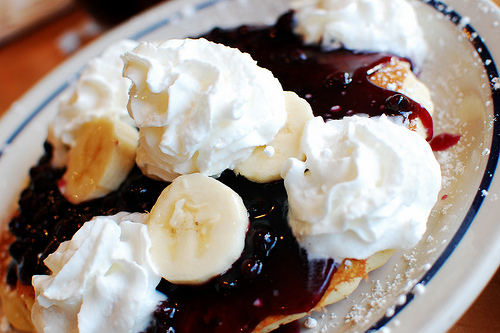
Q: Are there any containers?
A: No, there are no containers.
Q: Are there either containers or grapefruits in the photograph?
A: No, there are no containers or grapefruits.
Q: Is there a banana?
A: Yes, there is a banana.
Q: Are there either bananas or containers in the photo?
A: Yes, there is a banana.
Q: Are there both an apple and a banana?
A: No, there is a banana but no apples.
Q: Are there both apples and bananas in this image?
A: No, there is a banana but no apples.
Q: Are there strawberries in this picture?
A: No, there are no strawberries.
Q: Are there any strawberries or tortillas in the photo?
A: No, there are no strawberries or tortillas.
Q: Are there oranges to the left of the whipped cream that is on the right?
A: No, there is a banana to the left of the whipped cream.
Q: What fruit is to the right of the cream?
A: The fruit is a banana.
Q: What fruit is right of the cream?
A: The fruit is a banana.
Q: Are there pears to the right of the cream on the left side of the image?
A: No, there is a banana to the right of the cream.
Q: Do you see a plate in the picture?
A: Yes, there is a plate.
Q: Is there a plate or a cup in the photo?
A: Yes, there is a plate.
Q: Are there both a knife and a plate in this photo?
A: No, there is a plate but no knives.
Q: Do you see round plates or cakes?
A: Yes, there is a round plate.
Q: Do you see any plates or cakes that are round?
A: Yes, the plate is round.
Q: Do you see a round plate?
A: Yes, there is a round plate.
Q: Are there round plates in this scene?
A: Yes, there is a round plate.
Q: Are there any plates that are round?
A: Yes, there is a plate that is round.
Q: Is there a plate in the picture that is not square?
A: Yes, there is a round plate.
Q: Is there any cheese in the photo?
A: No, there is no cheese.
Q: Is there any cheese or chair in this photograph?
A: No, there are no cheese or chairs.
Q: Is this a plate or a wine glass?
A: This is a plate.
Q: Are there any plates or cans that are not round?
A: No, there is a plate but it is round.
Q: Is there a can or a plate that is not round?
A: No, there is a plate but it is round.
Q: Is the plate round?
A: Yes, the plate is round.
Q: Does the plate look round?
A: Yes, the plate is round.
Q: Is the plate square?
A: No, the plate is round.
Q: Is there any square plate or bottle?
A: No, there is a plate but it is round.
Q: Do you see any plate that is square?
A: No, there is a plate but it is round.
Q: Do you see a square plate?
A: No, there is a plate but it is round.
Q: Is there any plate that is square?
A: No, there is a plate but it is round.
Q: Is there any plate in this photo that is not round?
A: No, there is a plate but it is round.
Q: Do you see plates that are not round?
A: No, there is a plate but it is round.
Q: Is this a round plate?
A: Yes, this is a round plate.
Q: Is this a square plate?
A: No, this is a round plate.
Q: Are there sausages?
A: No, there are no sausages.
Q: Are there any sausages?
A: No, there are no sausages.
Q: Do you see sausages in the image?
A: No, there are no sausages.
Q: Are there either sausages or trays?
A: No, there are no sausages or trays.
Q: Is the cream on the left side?
A: Yes, the cream is on the left of the image.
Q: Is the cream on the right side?
A: No, the cream is on the left of the image.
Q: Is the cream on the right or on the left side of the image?
A: The cream is on the left of the image.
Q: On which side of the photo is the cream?
A: The cream is on the left of the image.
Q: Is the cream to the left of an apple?
A: No, the cream is to the left of the banana.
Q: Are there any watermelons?
A: No, there are no watermelons.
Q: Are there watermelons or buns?
A: No, there are no watermelons or buns.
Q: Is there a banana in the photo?
A: Yes, there is a banana.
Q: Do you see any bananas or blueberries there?
A: Yes, there is a banana.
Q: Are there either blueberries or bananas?
A: Yes, there is a banana.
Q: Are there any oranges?
A: No, there are no oranges.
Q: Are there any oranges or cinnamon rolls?
A: No, there are no oranges or cinnamon rolls.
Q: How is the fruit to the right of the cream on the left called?
A: The fruit is a banana.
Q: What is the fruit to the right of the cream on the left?
A: The fruit is a banana.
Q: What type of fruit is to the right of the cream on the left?
A: The fruit is a banana.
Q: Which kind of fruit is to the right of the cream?
A: The fruit is a banana.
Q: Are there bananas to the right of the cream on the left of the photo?
A: Yes, there is a banana to the right of the cream.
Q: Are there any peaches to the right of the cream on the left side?
A: No, there is a banana to the right of the cream.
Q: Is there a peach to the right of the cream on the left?
A: No, there is a banana to the right of the cream.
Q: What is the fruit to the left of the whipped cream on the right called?
A: The fruit is a banana.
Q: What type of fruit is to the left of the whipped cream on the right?
A: The fruit is a banana.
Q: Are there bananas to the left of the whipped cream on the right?
A: Yes, there is a banana to the left of the whipped cream.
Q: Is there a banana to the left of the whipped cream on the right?
A: Yes, there is a banana to the left of the whipped cream.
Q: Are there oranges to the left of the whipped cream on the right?
A: No, there is a banana to the left of the whipped cream.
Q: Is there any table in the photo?
A: Yes, there is a table.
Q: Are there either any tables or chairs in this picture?
A: Yes, there is a table.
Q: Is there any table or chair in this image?
A: Yes, there is a table.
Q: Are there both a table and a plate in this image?
A: Yes, there are both a table and a plate.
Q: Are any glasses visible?
A: No, there are no glasses.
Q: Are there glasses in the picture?
A: No, there are no glasses.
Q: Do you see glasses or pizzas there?
A: No, there are no glasses or pizzas.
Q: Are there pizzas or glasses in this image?
A: No, there are no glasses or pizzas.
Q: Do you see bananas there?
A: Yes, there is a banana.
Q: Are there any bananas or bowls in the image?
A: Yes, there is a banana.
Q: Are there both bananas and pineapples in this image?
A: No, there is a banana but no pineapples.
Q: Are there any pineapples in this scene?
A: No, there are no pineapples.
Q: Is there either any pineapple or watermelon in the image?
A: No, there are no pineapples or watermelons.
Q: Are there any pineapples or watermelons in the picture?
A: No, there are no pineapples or watermelons.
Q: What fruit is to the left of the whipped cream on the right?
A: The fruit is a banana.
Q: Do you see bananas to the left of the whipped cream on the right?
A: Yes, there is a banana to the left of the whipped cream.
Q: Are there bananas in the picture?
A: Yes, there is a banana.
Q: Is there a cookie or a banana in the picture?
A: Yes, there is a banana.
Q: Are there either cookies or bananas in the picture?
A: Yes, there is a banana.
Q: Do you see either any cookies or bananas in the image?
A: Yes, there is a banana.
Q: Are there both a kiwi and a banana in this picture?
A: No, there is a banana but no kiwis.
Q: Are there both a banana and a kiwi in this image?
A: No, there is a banana but no kiwis.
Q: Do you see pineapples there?
A: No, there are no pineapples.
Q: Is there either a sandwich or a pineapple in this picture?
A: No, there are no pineapples or sandwiches.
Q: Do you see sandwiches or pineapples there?
A: No, there are no pineapples or sandwiches.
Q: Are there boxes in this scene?
A: No, there are no boxes.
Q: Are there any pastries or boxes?
A: No, there are no boxes or pastries.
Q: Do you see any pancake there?
A: Yes, there is a pancake.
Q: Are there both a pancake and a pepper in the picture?
A: No, there is a pancake but no peppers.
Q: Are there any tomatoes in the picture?
A: No, there are no tomatoes.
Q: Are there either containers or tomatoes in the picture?
A: No, there are no tomatoes or containers.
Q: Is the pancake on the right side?
A: Yes, the pancake is on the right of the image.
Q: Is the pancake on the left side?
A: No, the pancake is on the right of the image.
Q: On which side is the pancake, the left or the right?
A: The pancake is on the right of the image.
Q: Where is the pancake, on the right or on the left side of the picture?
A: The pancake is on the right of the image.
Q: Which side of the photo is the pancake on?
A: The pancake is on the right of the image.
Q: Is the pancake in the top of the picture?
A: Yes, the pancake is in the top of the image.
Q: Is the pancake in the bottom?
A: No, the pancake is in the top of the image.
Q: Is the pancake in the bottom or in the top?
A: The pancake is in the top of the image.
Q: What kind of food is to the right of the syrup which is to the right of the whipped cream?
A: The food is a pancake.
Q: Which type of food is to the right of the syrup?
A: The food is a pancake.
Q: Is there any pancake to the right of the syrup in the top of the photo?
A: Yes, there is a pancake to the right of the syrup.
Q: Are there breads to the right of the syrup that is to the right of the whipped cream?
A: No, there is a pancake to the right of the syrup.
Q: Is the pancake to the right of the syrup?
A: Yes, the pancake is to the right of the syrup.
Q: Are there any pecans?
A: No, there are no pecans.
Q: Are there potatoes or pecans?
A: No, there are no pecans or potatoes.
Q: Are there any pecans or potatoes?
A: No, there are no pecans or potatoes.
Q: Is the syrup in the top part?
A: Yes, the syrup is in the top of the image.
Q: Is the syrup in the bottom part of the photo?
A: No, the syrup is in the top of the image.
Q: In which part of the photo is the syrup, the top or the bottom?
A: The syrup is in the top of the image.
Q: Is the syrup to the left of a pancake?
A: Yes, the syrup is to the left of a pancake.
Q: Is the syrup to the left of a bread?
A: No, the syrup is to the left of a pancake.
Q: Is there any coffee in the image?
A: No, there is no coffee.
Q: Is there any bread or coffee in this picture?
A: No, there are no coffee or breads.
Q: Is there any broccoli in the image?
A: No, there is no broccoli.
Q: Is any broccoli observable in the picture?
A: No, there is no broccoli.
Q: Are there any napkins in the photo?
A: No, there are no napkins.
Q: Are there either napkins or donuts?
A: No, there are no napkins or donuts.